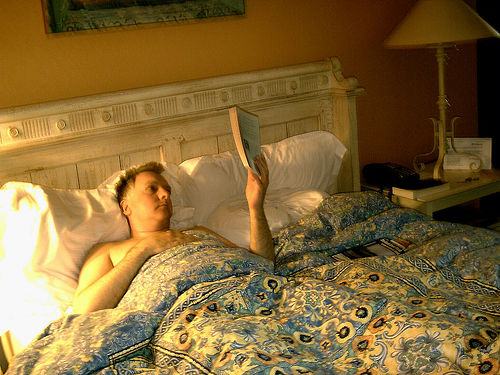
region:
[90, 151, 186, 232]
mans head on the pillow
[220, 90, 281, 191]
book in hand of man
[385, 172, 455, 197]
bible on the table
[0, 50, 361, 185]
cream headboard on the bed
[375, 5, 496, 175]
lamp on the table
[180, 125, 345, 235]
white pillow on the bed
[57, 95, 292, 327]
man laying in bed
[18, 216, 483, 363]
blanket covers a man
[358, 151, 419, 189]
black phone on table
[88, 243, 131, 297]
bare skin mans arm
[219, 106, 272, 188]
a book in a man's hand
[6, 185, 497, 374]
a blue and yellow patterned comforter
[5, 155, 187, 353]
a pillow behind a man's head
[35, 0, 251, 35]
a picture above a bed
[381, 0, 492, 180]
a lamp on a nightstand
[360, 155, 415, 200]
a black phone on a nightstand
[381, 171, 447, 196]
a book on a nightstand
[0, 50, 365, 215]
a white bed frame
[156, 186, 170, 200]
a nose on a man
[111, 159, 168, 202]
hair on a man's head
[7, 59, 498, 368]
man reading in bed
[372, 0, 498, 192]
lamp on a night stand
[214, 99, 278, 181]
book in man's hand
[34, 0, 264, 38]
framed art on wall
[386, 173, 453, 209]
book on a night stand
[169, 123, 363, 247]
white pillows on bed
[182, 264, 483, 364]
patterned comforter on bed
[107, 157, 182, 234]
face of a man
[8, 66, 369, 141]
headboard of a bed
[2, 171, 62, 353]
light casted on the pillow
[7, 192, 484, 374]
blue, yellow, black, and white comforter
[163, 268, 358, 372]
blue, yellow, black, and white pattern on comforter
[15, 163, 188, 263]
white pillow behind man's head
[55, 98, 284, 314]
man reading book in bed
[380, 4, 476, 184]
decorative lamp on night stand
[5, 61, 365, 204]
cream and brown wooden headboard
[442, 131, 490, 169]
upright paper on night stand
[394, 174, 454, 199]
book laying on night stand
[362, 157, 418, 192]
black carrying case on night stand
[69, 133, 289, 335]
shirtless man in bed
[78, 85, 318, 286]
man holds book in left hand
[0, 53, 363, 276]
cream-colored headboard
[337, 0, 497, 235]
nightstand next to the bed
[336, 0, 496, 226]
lamp on nightstand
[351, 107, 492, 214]
black phone on nightstand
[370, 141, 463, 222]
book next to phone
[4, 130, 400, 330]
white pillowcases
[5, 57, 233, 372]
sunlight reflected on pillows and blanket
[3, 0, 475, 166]
yellow wall